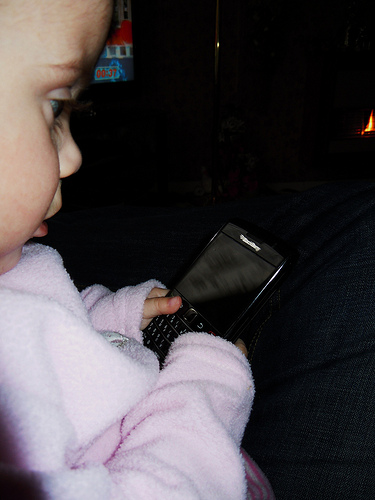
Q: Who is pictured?
A: A baby.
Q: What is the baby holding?
A: A cell phone.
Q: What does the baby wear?
A: Pink sweater.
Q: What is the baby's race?
A: Caucasian.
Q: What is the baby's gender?
A: Female.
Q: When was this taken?
A: After sunset.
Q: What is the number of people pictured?
A: One.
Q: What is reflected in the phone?
A: The indoor lighting.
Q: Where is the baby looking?
A: Downward.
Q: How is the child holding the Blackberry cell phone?
A: With both hands.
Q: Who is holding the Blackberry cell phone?
A: The child.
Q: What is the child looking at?
A: The Blackberry.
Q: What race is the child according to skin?
A: Caucasian.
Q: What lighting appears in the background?
A: No lighting.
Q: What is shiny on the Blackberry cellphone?
A: The screen.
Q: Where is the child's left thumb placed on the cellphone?
A: Just above the keyboard.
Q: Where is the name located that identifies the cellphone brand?
A: Top of the cellphone.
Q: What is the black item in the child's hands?
A: Blackberry cellphone.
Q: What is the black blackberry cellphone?
A: Shiny.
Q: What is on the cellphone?
A: Small baby.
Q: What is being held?
A: Blackberry cellphone.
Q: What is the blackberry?
A: Phone.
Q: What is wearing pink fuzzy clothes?
A: Baby.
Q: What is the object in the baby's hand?
A: A cell phone.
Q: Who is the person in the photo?
A: A baby.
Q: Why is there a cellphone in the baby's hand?
A: The baby is looking at the cellphone.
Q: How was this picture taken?
A: With a camera.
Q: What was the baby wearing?
A: Baby clothes.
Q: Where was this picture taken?
A: In the dark.